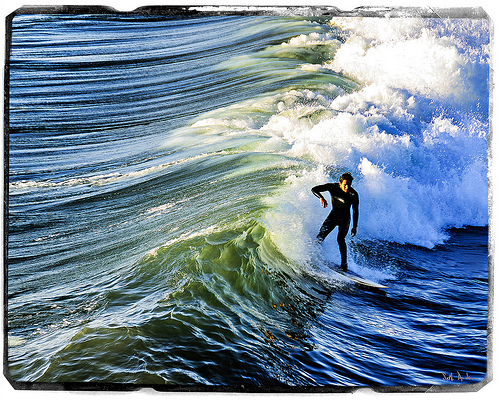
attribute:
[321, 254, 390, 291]
surfboard — white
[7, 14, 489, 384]
water — blue, white, rushing, wave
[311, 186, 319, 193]
elbow — bent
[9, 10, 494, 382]
ocean — green 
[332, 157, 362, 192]
brown hair — dark 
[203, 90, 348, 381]
waves — ocean